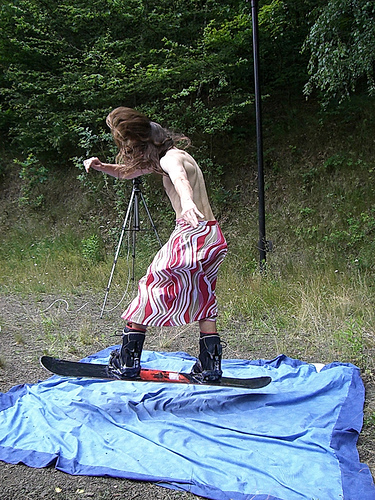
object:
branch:
[192, 102, 234, 142]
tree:
[5, 1, 264, 200]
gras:
[0, 132, 375, 360]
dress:
[121, 218, 228, 327]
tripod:
[100, 180, 163, 319]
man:
[83, 106, 228, 382]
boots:
[108, 322, 146, 378]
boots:
[192, 331, 223, 382]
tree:
[299, 0, 374, 118]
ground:
[0, 167, 375, 500]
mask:
[106, 106, 174, 173]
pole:
[251, 26, 265, 269]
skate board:
[39, 355, 271, 389]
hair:
[106, 106, 191, 177]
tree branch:
[67, 118, 97, 152]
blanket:
[0, 344, 373, 500]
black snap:
[118, 338, 144, 374]